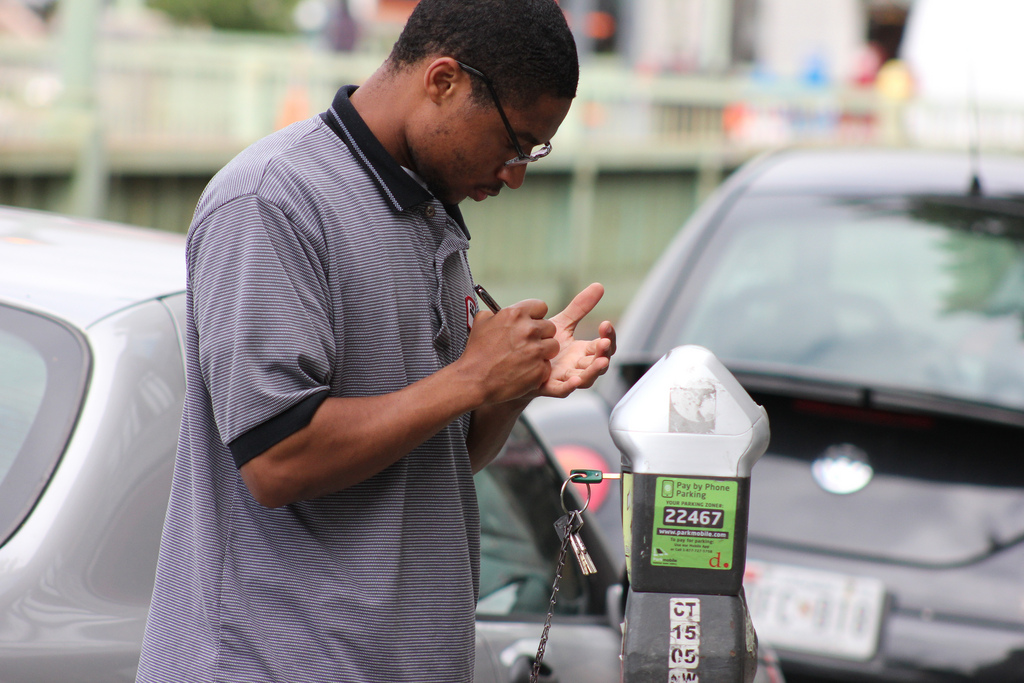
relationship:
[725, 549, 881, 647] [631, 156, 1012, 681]
plate on car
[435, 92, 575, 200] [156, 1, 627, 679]
face of man